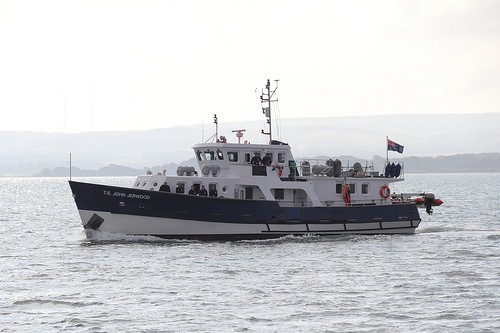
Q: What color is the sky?
A: White.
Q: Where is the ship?
A: In the water.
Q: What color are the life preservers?
A: Red.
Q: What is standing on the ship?
A: People.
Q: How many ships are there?
A: One.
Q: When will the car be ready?
A: No car.